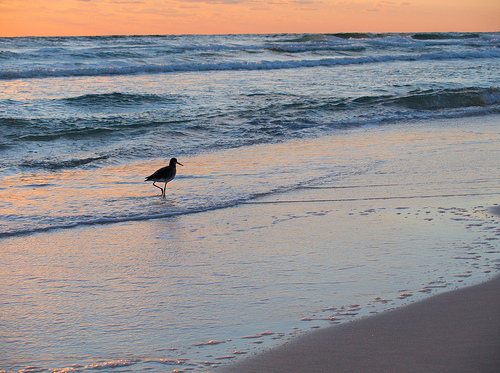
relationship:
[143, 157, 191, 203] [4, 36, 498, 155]
bird in water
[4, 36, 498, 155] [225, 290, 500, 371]
water on beach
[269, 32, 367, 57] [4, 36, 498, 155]
waves on water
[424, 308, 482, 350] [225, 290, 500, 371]
sand on beach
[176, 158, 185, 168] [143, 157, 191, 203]
bill on bird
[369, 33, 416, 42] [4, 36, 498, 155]
foam on water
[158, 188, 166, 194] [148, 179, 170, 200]
yellow bird legs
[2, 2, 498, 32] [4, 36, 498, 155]
sky above water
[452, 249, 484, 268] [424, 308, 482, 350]
rock on sand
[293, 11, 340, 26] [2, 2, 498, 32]
cloud in sky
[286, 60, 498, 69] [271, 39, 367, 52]
edge of wave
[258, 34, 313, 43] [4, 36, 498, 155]
part of water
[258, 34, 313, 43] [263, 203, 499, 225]
part of shore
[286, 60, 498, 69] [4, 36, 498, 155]
edge of water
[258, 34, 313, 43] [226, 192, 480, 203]
part of liner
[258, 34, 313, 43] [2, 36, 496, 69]
part of sea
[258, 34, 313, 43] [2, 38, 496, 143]
part of ocean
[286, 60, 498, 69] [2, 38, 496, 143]
edge of ocean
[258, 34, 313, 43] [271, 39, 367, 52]
part of wave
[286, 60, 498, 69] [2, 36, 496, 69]
edge of sea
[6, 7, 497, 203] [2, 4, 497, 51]
picture at sunset